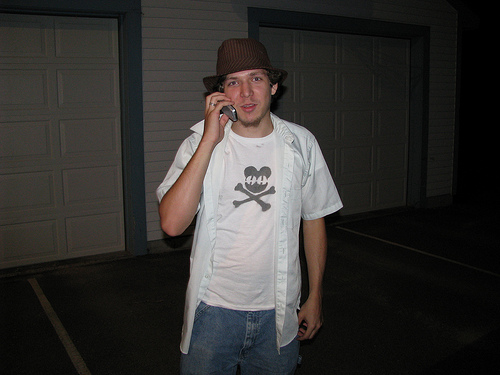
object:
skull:
[244, 166, 272, 193]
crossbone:
[233, 165, 276, 212]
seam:
[278, 148, 289, 335]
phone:
[217, 89, 238, 121]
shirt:
[154, 110, 344, 355]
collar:
[190, 112, 295, 145]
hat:
[202, 38, 286, 93]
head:
[220, 64, 277, 127]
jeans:
[180, 298, 303, 374]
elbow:
[161, 220, 183, 237]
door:
[250, 9, 412, 218]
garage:
[1, 5, 498, 374]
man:
[153, 37, 339, 375]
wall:
[142, 3, 252, 242]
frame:
[0, 0, 150, 254]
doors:
[0, 16, 131, 270]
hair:
[204, 66, 285, 115]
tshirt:
[202, 124, 278, 312]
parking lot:
[3, 198, 499, 374]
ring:
[209, 103, 215, 107]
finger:
[214, 101, 233, 109]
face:
[219, 70, 271, 126]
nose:
[240, 82, 253, 98]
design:
[232, 166, 275, 213]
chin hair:
[236, 113, 262, 126]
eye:
[228, 80, 240, 87]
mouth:
[240, 102, 259, 112]